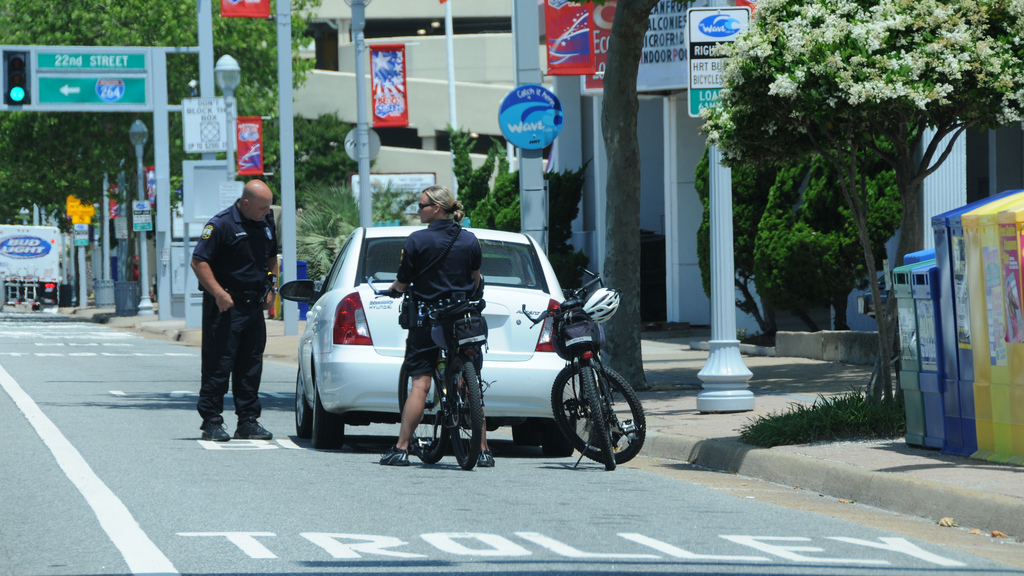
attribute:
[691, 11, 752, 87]
sign — small, white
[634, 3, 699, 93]
sign — large, white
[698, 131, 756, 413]
pole — large, white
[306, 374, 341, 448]
wheel — black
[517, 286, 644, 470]
bike — black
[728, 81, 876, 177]
leaves — green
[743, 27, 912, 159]
leaves — green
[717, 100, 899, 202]
leaves — green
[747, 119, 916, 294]
leaves — green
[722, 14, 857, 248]
leaves — green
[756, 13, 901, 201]
leaves — green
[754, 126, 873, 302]
leaves — green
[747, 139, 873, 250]
leaves — green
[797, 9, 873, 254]
leaves — green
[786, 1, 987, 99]
leaves — green